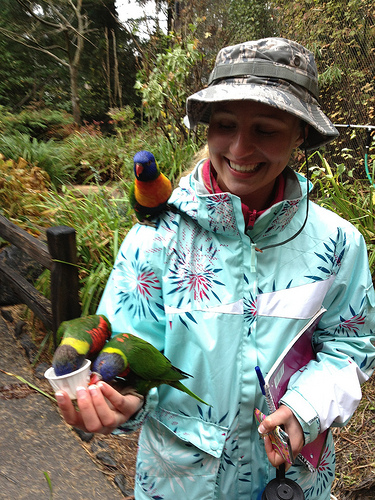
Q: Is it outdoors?
A: Yes, it is outdoors.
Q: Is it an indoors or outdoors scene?
A: It is outdoors.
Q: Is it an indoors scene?
A: No, it is outdoors.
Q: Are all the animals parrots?
A: Yes, all the animals are parrots.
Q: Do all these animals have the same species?
A: Yes, all the animals are parrots.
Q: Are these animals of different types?
A: No, all the animals are parrots.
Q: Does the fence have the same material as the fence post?
A: Yes, both the fence and the fence post are made of wood.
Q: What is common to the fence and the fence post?
A: The material, both the fence and the fence post are wooden.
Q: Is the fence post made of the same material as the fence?
A: Yes, both the fence post and the fence are made of wood.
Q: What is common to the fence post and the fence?
A: The material, both the fence post and the fence are wooden.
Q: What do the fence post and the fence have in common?
A: The material, both the fence post and the fence are wooden.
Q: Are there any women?
A: Yes, there is a woman.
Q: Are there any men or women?
A: Yes, there is a woman.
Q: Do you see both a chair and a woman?
A: No, there is a woman but no chairs.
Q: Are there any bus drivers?
A: No, there are no bus drivers.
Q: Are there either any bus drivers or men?
A: No, there are no bus drivers or men.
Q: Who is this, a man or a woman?
A: This is a woman.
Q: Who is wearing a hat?
A: The woman is wearing a hat.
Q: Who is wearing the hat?
A: The woman is wearing a hat.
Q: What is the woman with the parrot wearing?
A: The woman is wearing a hat.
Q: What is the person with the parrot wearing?
A: The woman is wearing a hat.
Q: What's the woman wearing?
A: The woman is wearing a hat.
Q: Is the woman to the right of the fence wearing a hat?
A: Yes, the woman is wearing a hat.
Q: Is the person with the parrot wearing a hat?
A: Yes, the woman is wearing a hat.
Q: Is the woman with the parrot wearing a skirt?
A: No, the woman is wearing a hat.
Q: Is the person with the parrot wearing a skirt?
A: No, the woman is wearing a hat.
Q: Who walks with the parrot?
A: The woman walks with the parrot.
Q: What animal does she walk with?
A: The woman walks with a parrot.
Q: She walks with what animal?
A: The woman walks with a parrot.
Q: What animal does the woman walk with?
A: The woman walks with a parrot.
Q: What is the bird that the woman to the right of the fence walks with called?
A: The bird is a parrot.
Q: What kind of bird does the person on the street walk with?
A: The woman walks with a parrot.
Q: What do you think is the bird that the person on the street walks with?
A: The bird is a parrot.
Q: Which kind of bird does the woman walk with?
A: The woman walks with a parrot.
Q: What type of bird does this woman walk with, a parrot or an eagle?
A: The woman walks with a parrot.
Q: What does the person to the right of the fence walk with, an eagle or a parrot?
A: The woman walks with a parrot.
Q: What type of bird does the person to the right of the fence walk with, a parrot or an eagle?
A: The woman walks with a parrot.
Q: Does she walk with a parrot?
A: Yes, the woman walks with a parrot.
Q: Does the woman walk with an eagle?
A: No, the woman walks with a parrot.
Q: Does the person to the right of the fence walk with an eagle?
A: No, the woman walks with a parrot.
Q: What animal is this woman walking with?
A: The woman is walking with a parrot.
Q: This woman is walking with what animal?
A: The woman is walking with a parrot.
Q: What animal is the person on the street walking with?
A: The woman is walking with a parrot.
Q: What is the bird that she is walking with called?
A: The bird is a parrot.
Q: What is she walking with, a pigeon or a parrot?
A: The woman is walking with a parrot.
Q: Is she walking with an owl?
A: No, the woman is walking with a parrot.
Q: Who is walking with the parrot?
A: The woman is walking with the parrot.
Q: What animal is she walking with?
A: The woman is walking with a parrot.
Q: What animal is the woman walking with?
A: The woman is walking with a parrot.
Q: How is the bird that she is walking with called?
A: The bird is a parrot.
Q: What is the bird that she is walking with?
A: The bird is a parrot.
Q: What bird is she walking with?
A: The woman is walking with a parrot.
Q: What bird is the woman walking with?
A: The woman is walking with a parrot.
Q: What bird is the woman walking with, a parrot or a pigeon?
A: The woman is walking with a parrot.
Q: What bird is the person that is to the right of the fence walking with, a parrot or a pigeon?
A: The woman is walking with a parrot.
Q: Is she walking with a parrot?
A: Yes, the woman is walking with a parrot.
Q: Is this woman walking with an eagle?
A: No, the woman is walking with a parrot.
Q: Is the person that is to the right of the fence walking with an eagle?
A: No, the woman is walking with a parrot.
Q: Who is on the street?
A: The woman is on the street.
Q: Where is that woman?
A: The woman is on the street.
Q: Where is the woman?
A: The woman is on the street.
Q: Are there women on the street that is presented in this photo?
A: Yes, there is a woman on the street.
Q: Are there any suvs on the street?
A: No, there is a woman on the street.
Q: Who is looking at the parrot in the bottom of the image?
A: The woman is looking at the parrot.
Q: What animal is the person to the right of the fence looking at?
A: The woman is looking at the parrot.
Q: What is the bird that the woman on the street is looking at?
A: The bird is a parrot.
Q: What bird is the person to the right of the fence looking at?
A: The woman is looking at the parrot.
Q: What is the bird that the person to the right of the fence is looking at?
A: The bird is a parrot.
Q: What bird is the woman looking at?
A: The woman is looking at the parrot.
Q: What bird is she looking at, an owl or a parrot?
A: The woman is looking at a parrot.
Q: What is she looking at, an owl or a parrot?
A: The woman is looking at a parrot.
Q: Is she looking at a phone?
A: No, the woman is looking at the parrot.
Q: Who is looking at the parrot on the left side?
A: The woman is looking at the parrot.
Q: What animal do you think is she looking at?
A: The woman is looking at the parrot.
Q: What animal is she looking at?
A: The woman is looking at the parrot.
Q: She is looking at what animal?
A: The woman is looking at the parrot.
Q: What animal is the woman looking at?
A: The woman is looking at the parrot.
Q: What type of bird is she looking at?
A: The woman is looking at the parrot.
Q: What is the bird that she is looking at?
A: The bird is a parrot.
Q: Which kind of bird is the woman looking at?
A: The woman is looking at the parrot.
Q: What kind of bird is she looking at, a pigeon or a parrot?
A: The woman is looking at a parrot.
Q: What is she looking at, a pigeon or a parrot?
A: The woman is looking at a parrot.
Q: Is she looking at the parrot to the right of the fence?
A: Yes, the woman is looking at the parrot.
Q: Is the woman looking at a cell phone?
A: No, the woman is looking at the parrot.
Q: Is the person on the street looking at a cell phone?
A: No, the woman is looking at the parrot.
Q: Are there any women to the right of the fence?
A: Yes, there is a woman to the right of the fence.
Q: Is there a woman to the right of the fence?
A: Yes, there is a woman to the right of the fence.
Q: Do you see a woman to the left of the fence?
A: No, the woman is to the right of the fence.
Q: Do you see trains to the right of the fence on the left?
A: No, there is a woman to the right of the fence.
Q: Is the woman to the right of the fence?
A: Yes, the woman is to the right of the fence.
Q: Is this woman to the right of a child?
A: No, the woman is to the right of the fence.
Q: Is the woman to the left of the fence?
A: No, the woman is to the right of the fence.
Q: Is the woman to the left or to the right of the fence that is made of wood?
A: The woman is to the right of the fence.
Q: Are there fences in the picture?
A: Yes, there is a fence.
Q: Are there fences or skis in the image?
A: Yes, there is a fence.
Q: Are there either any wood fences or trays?
A: Yes, there is a wood fence.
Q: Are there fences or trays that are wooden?
A: Yes, the fence is wooden.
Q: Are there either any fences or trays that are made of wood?
A: Yes, the fence is made of wood.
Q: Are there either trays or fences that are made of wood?
A: Yes, the fence is made of wood.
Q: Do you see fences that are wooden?
A: Yes, there is a wood fence.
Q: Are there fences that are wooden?
A: Yes, there is a fence that is wooden.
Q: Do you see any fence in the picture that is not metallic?
A: Yes, there is a wooden fence.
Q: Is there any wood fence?
A: Yes, there is a fence that is made of wood.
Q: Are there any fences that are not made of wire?
A: Yes, there is a fence that is made of wood.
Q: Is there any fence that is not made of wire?
A: Yes, there is a fence that is made of wood.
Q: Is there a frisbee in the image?
A: No, there are no frisbees.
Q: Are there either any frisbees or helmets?
A: No, there are no frisbees or helmets.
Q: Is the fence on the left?
A: Yes, the fence is on the left of the image.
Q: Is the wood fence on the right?
A: No, the fence is on the left of the image.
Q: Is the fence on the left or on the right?
A: The fence is on the left of the image.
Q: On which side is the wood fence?
A: The fence is on the left of the image.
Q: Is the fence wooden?
A: Yes, the fence is wooden.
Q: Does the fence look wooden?
A: Yes, the fence is wooden.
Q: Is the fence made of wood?
A: Yes, the fence is made of wood.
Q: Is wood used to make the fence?
A: Yes, the fence is made of wood.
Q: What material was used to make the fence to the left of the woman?
A: The fence is made of wood.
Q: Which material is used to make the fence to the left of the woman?
A: The fence is made of wood.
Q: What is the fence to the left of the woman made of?
A: The fence is made of wood.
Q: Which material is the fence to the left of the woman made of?
A: The fence is made of wood.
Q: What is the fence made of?
A: The fence is made of wood.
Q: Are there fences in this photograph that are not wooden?
A: No, there is a fence but it is wooden.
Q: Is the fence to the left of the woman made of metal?
A: No, the fence is made of wood.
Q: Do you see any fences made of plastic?
A: No, there is a fence but it is made of wood.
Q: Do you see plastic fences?
A: No, there is a fence but it is made of wood.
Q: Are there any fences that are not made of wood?
A: No, there is a fence but it is made of wood.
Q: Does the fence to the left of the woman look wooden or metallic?
A: The fence is wooden.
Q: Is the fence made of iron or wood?
A: The fence is made of wood.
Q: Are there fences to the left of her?
A: Yes, there is a fence to the left of the woman.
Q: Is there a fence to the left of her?
A: Yes, there is a fence to the left of the woman.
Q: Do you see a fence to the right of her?
A: No, the fence is to the left of the woman.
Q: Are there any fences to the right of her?
A: No, the fence is to the left of the woman.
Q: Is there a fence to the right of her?
A: No, the fence is to the left of the woman.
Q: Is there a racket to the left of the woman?
A: No, there is a fence to the left of the woman.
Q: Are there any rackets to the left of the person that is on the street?
A: No, there is a fence to the left of the woman.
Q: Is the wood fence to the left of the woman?
A: Yes, the fence is to the left of the woman.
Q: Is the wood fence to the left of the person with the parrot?
A: Yes, the fence is to the left of the woman.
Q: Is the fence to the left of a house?
A: No, the fence is to the left of the woman.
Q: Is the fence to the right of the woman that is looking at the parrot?
A: No, the fence is to the left of the woman.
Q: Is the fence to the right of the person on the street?
A: No, the fence is to the left of the woman.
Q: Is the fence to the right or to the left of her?
A: The fence is to the left of the woman.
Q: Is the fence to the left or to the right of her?
A: The fence is to the left of the woman.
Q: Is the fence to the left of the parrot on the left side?
A: Yes, the fence is to the left of the parrot.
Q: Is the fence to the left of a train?
A: No, the fence is to the left of the parrot.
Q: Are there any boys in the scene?
A: No, there are no boys.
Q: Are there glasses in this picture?
A: No, there are no glasses.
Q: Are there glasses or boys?
A: No, there are no glasses or boys.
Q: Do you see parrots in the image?
A: Yes, there is a parrot.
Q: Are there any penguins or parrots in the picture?
A: Yes, there is a parrot.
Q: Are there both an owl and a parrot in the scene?
A: No, there is a parrot but no owls.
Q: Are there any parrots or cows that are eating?
A: Yes, the parrot is eating.